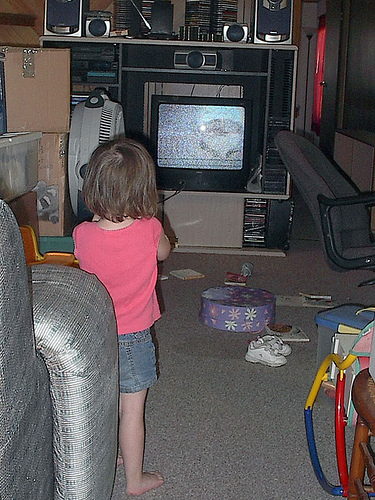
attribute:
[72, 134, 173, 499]
girl — barefoot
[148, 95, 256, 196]
television — blurry, on, black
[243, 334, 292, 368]
tennis shoes — white, girls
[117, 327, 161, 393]
shorts — blue jean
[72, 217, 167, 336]
top — pink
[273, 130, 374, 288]
chair — grey, gray, black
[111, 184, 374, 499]
carpet — gray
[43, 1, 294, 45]
speakers — silver, black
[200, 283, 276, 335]
box — purple, round, hat box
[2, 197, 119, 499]
couch — silver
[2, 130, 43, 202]
box — plastic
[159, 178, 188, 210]
cables — black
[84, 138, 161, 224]
hair — brown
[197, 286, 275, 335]
flowers — pink, white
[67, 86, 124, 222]
fan — white